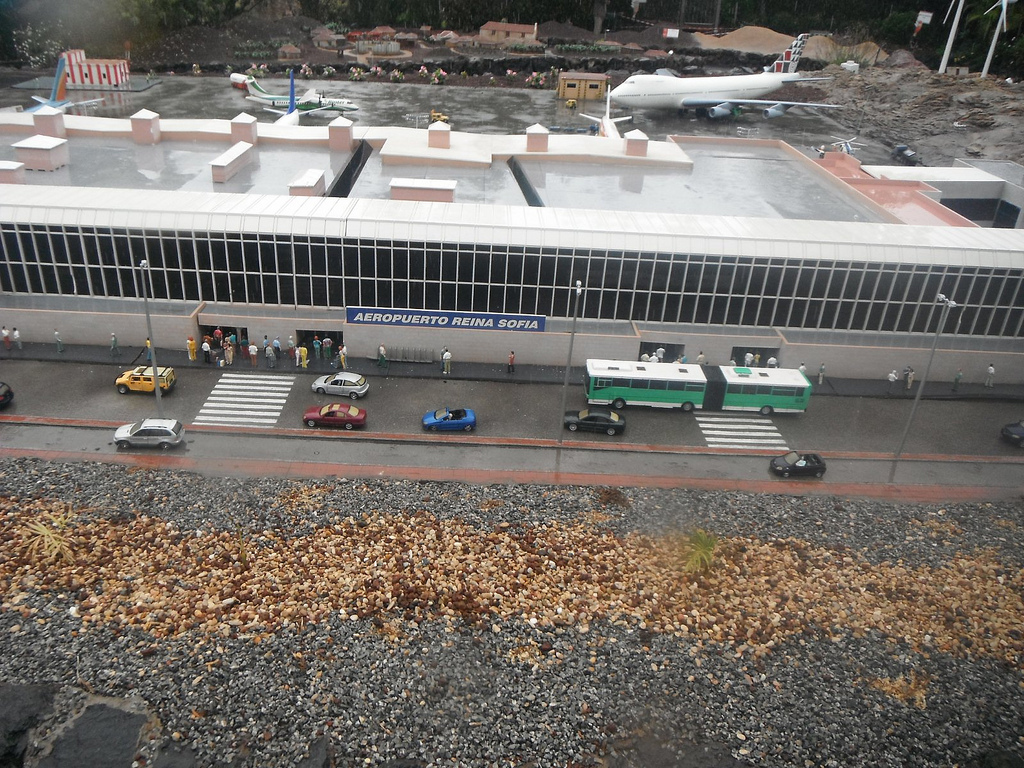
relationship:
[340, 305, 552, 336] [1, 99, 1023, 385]
sign on building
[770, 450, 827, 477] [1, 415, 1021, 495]
car driving on road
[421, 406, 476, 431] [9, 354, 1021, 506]
car on road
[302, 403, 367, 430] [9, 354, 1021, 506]
car on road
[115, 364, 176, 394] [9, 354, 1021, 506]
car on road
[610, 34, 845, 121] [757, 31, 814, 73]
airplane with tail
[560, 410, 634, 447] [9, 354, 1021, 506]
car on road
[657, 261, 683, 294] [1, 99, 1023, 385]
window on building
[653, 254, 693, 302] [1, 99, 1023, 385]
window on building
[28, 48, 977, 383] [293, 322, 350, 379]
airport has a right entrance way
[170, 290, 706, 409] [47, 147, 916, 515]
wall on side of a building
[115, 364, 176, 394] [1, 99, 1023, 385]
car in front of building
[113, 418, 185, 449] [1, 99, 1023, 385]
car in front of building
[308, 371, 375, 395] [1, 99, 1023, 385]
car in front of building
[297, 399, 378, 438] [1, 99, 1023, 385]
car in front of building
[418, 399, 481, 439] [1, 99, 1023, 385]
car in front of building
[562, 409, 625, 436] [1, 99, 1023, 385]
car in front of building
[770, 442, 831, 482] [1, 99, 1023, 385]
car in front of building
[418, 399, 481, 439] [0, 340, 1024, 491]
car on road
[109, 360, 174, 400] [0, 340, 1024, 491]
car on road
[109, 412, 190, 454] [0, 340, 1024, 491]
car on road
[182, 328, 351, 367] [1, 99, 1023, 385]
people in front of building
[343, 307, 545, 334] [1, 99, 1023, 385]
sign on front of building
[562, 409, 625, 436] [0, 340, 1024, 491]
car on road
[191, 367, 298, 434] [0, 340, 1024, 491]
crosswalk on road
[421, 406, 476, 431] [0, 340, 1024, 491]
car on road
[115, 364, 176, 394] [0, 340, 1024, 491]
car on road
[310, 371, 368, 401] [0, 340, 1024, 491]
car on road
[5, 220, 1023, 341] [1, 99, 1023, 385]
windows on building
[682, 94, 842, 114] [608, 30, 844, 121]
wing on plane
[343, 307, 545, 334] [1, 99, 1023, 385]
sign on building